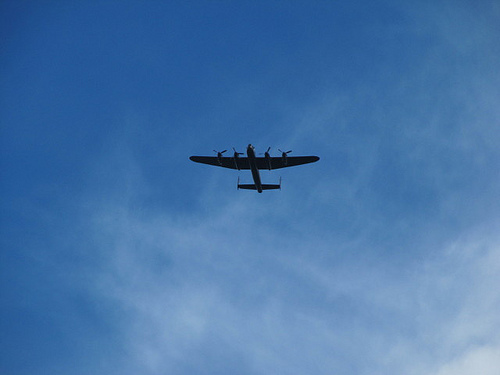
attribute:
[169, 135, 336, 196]
plane — big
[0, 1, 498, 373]
sky — clear, bright, blue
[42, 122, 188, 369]
clouds — thin, white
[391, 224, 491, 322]
clouds — white, thin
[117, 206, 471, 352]
clouds — thin, white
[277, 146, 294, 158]
propeller — far left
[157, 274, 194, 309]
cloud — white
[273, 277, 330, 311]
cloud — white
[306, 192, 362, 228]
cloud — white, thin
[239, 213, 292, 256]
cloud — white, thin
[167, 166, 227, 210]
cloud — white, thin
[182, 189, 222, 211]
cloud — thin, white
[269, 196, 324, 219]
cloud — thin, white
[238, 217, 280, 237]
cloud — thin, white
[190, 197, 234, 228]
cloud — white, thin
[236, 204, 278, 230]
cloud — white, thin